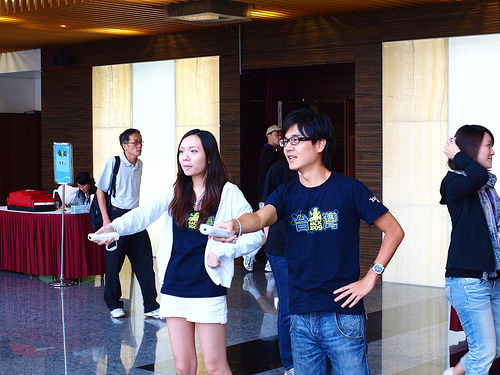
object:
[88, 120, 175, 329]
people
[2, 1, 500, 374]
room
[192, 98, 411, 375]
man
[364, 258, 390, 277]
watch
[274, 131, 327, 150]
spectacles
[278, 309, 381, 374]
jeans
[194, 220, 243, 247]
remotes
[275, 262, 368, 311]
waist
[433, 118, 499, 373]
woman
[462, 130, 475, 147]
hair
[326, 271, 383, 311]
hand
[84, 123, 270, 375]
lady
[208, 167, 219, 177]
hair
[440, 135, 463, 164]
hand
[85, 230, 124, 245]
controller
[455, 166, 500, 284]
scarf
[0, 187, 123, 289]
table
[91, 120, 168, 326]
man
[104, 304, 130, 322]
shoes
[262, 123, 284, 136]
cap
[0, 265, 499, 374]
floor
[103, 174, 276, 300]
jacket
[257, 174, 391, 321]
shirt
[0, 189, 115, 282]
tablecloth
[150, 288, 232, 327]
shorts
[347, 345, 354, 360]
part